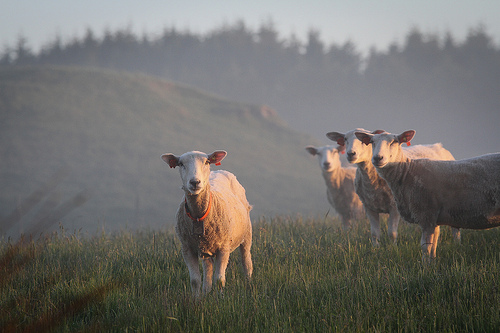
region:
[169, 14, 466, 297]
four goats standing in a field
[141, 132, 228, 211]
a goat with a tag in its ear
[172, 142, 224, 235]
a goat wearing a collar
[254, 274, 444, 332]
tall grass in a field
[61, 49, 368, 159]
fog over a hills side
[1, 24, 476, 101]
row of green trees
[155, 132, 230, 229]
a goat with a tag attached to its ear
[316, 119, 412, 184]
two goats with tags on their ears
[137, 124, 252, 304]
a goat in a field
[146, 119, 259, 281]
a white goat standing in a field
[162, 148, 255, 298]
Sheep with an orange collar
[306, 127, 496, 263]
Group of three sheep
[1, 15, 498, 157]
Tall, out of focus trees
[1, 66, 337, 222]
Grassy hill in the distance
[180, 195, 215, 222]
Orange collar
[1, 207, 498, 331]
Field of tall grass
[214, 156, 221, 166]
Orange ear tag on a sheep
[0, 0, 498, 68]
Grayish blue sky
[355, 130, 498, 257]
Front sheep in a group of three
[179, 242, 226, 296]
Front legs of a sheep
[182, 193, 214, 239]
a bell on neck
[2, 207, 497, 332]
a grassy field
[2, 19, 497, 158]
the tall full trees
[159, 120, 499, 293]
the cows have been tag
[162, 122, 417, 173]
all pointy ears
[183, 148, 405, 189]
black small round noses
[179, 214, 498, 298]
the legs of cows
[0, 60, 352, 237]
a small grassy hill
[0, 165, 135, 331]
branches from a bush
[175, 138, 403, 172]
the slanted eyes of sheep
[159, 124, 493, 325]
Four sheep standing on grass.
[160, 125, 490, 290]
Four shorn sheep.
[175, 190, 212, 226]
A red collar on a sheep.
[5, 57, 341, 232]
A hill behind the sheep.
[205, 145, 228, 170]
A red tag in a sheep's ear.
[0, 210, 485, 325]
Tall grass on the ground.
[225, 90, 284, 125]
A rock formation on the hill.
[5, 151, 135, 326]
Strands of long grass.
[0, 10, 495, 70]
Trees on the hilltop.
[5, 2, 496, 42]
Gray skies above trees.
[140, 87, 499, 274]
four sheep standing around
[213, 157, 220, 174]
red tag in sheeps ear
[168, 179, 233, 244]
orange collar around the neck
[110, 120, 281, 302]
one sheep stands alone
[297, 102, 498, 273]
three sheep stand together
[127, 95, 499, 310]
four sheep standing in grass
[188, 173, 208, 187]
black nose of sheep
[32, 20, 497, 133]
a row of trees in the distance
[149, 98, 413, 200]
four heads on sheep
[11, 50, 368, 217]
a hill behind the sheep